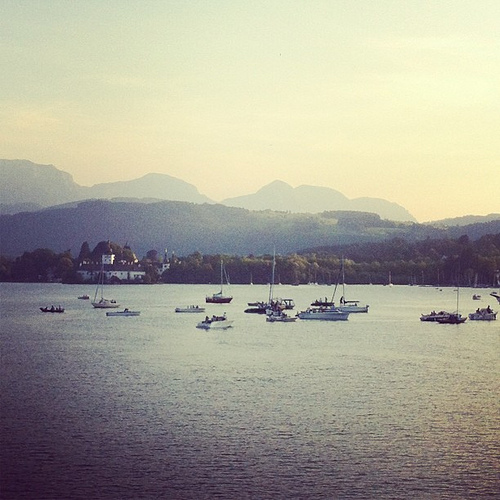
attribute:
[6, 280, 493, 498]
water — calm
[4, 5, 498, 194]
sky — hazy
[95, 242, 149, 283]
house — white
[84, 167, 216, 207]
mountain — hazy, gray blue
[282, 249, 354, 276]
trees — green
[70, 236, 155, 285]
house — white